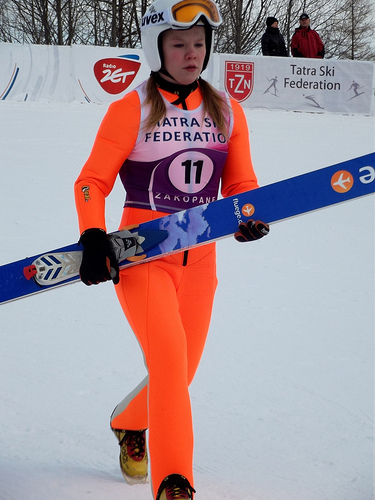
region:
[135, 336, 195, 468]
the pants are orange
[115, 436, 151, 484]
the shoes are yellow and orange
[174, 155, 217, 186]
number 11 is on the circle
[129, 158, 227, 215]
the shirt is purple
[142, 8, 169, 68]
the helmet is white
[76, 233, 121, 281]
the gloves are black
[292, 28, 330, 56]
the jacket is red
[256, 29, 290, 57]
the jacket is black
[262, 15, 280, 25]
the marvin is black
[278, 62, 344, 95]
the letters say skitetra federation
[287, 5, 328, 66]
This is a person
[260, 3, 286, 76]
This is a person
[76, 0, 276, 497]
This is a person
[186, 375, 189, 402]
This is a person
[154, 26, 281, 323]
This is a person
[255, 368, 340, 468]
A snow covered ground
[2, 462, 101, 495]
A snow covered ground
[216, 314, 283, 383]
A snow covered ground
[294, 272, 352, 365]
A snow covered ground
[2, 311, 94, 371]
A snow covered ground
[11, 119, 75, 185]
A snow covered ground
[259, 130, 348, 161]
A snow covered ground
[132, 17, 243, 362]
A woman in an orange swim suit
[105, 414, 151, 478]
A heavy brown shoe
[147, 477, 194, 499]
A heavy brown shoe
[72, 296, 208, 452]
the pants are orange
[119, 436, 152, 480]
the shoes are yellow and red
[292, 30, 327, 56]
the jacket is red in color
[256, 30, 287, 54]
the jacket is black in color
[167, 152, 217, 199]
number 11 is on the shirt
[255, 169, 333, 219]
the board is blue in color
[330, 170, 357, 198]
the circle is orange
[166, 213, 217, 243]
cloud is on the surface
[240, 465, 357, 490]
the snow is white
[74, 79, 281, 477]
orange suit of skier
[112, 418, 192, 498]
black, red, and yellow shoes of skier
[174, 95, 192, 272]
black zipper on orange ski suit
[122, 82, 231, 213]
race bib of skier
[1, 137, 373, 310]
blue skis being carried by skier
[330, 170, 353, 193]
white plane logo on orange background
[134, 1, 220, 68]
white helmet of skier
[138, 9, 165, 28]
black lettering on white background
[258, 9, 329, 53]
men standing along barrier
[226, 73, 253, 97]
white lettering on red background